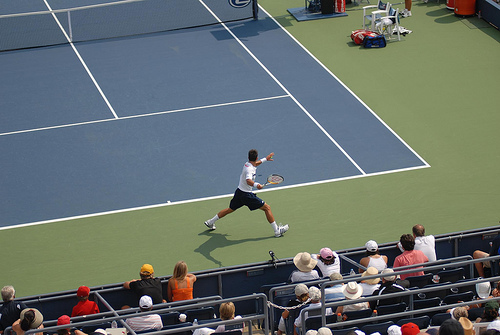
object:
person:
[123, 264, 163, 306]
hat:
[140, 264, 154, 276]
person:
[71, 286, 99, 318]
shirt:
[72, 299, 100, 315]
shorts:
[228, 187, 265, 210]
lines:
[199, 0, 365, 174]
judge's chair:
[363, 0, 392, 29]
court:
[0, 0, 500, 306]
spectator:
[393, 233, 429, 280]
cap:
[365, 240, 376, 252]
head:
[362, 240, 380, 257]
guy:
[204, 148, 291, 237]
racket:
[262, 174, 284, 187]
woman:
[311, 247, 340, 278]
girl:
[167, 261, 197, 302]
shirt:
[393, 250, 429, 281]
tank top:
[171, 276, 194, 300]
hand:
[257, 184, 263, 189]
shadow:
[194, 229, 276, 268]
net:
[0, 0, 259, 52]